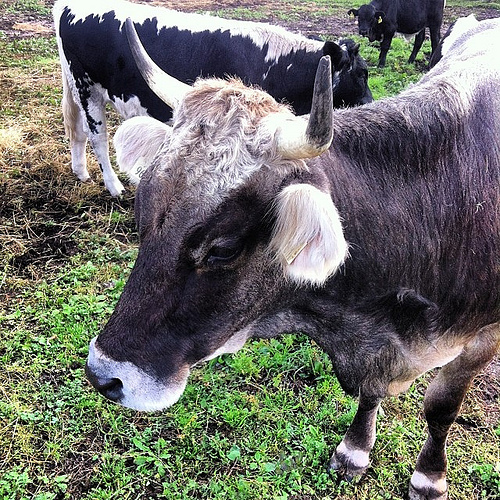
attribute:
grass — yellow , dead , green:
[2, 0, 499, 500]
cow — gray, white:
[45, 55, 498, 417]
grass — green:
[24, 226, 125, 331]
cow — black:
[346, 0, 445, 70]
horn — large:
[282, 50, 346, 162]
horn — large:
[108, 11, 195, 113]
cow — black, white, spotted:
[53, 6, 373, 204]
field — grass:
[18, 212, 255, 485]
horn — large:
[122, 15, 194, 115]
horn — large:
[274, 53, 334, 161]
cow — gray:
[87, 17, 497, 494]